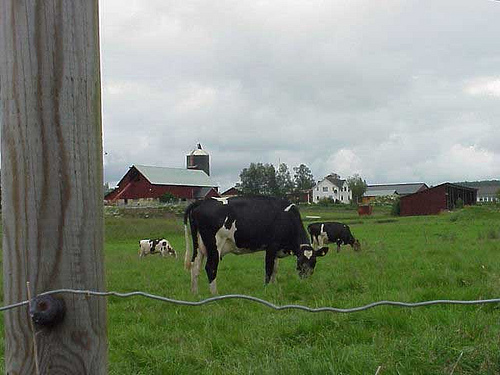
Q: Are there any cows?
A: Yes, there is a cow.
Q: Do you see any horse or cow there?
A: Yes, there is a cow.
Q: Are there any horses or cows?
A: Yes, there is a cow.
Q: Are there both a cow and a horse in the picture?
A: No, there is a cow but no horses.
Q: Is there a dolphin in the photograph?
A: No, there are no dolphins.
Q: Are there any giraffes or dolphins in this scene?
A: No, there are no dolphins or giraffes.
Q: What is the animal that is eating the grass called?
A: The animal is a cow.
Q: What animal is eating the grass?
A: The animal is a cow.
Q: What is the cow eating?
A: The cow is eating grass.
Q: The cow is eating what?
A: The cow is eating grass.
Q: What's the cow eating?
A: The cow is eating grass.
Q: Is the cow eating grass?
A: Yes, the cow is eating grass.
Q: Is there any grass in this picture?
A: Yes, there is grass.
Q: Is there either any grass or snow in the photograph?
A: Yes, there is grass.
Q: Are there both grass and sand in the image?
A: No, there is grass but no sand.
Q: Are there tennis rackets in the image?
A: No, there are no tennis rackets.